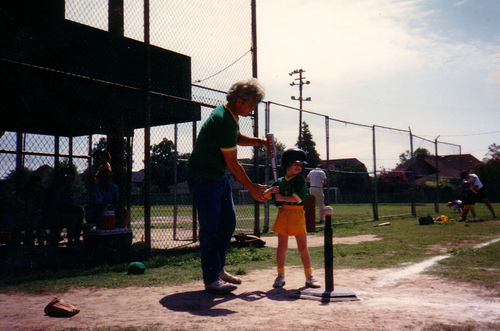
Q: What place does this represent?
A: It represents the field.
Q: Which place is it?
A: It is a field.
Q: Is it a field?
A: Yes, it is a field.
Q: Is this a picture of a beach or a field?
A: It is showing a field.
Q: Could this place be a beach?
A: No, it is a field.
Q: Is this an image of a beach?
A: No, the picture is showing a field.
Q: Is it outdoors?
A: Yes, it is outdoors.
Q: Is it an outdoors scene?
A: Yes, it is outdoors.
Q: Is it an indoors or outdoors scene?
A: It is outdoors.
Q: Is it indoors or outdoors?
A: It is outdoors.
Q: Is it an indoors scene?
A: No, it is outdoors.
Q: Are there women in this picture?
A: No, there are no women.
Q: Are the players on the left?
A: Yes, the players are on the left of the image.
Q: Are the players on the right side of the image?
A: No, the players are on the left of the image.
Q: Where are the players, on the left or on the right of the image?
A: The players are on the left of the image.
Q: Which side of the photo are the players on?
A: The players are on the left of the image.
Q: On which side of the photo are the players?
A: The players are on the left of the image.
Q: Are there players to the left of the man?
A: Yes, there are players to the left of the man.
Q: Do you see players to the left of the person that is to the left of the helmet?
A: Yes, there are players to the left of the man.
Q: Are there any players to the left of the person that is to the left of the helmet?
A: Yes, there are players to the left of the man.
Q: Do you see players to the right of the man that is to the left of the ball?
A: No, the players are to the left of the man.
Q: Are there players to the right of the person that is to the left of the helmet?
A: No, the players are to the left of the man.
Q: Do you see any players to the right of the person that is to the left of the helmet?
A: No, the players are to the left of the man.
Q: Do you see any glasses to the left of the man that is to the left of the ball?
A: No, there are players to the left of the man.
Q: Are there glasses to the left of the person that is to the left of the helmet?
A: No, there are players to the left of the man.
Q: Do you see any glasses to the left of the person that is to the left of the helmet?
A: No, there are players to the left of the man.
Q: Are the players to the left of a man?
A: Yes, the players are to the left of a man.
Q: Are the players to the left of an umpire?
A: No, the players are to the left of a man.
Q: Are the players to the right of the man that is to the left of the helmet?
A: No, the players are to the left of the man.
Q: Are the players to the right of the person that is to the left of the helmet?
A: No, the players are to the left of the man.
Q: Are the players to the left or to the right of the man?
A: The players are to the left of the man.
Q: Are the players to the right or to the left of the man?
A: The players are to the left of the man.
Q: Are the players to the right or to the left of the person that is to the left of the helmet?
A: The players are to the left of the man.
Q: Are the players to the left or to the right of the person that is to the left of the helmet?
A: The players are to the left of the man.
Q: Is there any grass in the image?
A: Yes, there is grass.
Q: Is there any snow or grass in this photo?
A: Yes, there is grass.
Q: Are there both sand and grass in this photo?
A: No, there is grass but no sand.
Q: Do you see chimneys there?
A: No, there are no chimneys.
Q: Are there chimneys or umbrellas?
A: No, there are no chimneys or umbrellas.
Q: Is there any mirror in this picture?
A: No, there are no mirrors.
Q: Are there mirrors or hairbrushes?
A: No, there are no mirrors or hairbrushes.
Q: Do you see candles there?
A: No, there are no candles.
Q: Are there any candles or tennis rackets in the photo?
A: No, there are no candles or tennis rackets.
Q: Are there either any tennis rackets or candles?
A: No, there are no candles or tennis rackets.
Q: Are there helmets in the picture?
A: Yes, there is a helmet.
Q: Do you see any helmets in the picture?
A: Yes, there is a helmet.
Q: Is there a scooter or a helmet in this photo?
A: Yes, there is a helmet.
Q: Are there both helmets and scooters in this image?
A: No, there is a helmet but no scooters.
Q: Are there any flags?
A: No, there are no flags.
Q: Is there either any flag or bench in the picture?
A: No, there are no flags or benches.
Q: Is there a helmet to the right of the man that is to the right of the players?
A: Yes, there is a helmet to the right of the man.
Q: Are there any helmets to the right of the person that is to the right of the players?
A: Yes, there is a helmet to the right of the man.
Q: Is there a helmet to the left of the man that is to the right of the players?
A: No, the helmet is to the right of the man.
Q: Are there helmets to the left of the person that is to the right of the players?
A: No, the helmet is to the right of the man.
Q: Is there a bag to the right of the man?
A: No, there is a helmet to the right of the man.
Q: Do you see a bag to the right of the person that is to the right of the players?
A: No, there is a helmet to the right of the man.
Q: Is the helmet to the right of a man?
A: Yes, the helmet is to the right of a man.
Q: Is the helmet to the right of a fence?
A: No, the helmet is to the right of a man.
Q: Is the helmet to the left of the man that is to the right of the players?
A: No, the helmet is to the right of the man.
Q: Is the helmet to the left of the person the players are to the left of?
A: No, the helmet is to the right of the man.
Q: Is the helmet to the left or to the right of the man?
A: The helmet is to the right of the man.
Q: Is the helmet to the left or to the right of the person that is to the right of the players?
A: The helmet is to the right of the man.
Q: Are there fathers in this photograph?
A: No, there are no fathers.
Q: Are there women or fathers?
A: No, there are no fathers or women.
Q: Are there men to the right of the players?
A: Yes, there is a man to the right of the players.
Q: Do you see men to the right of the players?
A: Yes, there is a man to the right of the players.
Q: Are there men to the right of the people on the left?
A: Yes, there is a man to the right of the players.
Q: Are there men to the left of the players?
A: No, the man is to the right of the players.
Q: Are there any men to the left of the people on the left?
A: No, the man is to the right of the players.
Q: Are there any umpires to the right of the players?
A: No, there is a man to the right of the players.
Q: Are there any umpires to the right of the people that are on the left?
A: No, there is a man to the right of the players.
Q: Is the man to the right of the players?
A: Yes, the man is to the right of the players.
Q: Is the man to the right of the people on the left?
A: Yes, the man is to the right of the players.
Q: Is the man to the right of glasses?
A: No, the man is to the right of the players.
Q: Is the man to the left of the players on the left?
A: No, the man is to the right of the players.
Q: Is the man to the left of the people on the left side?
A: No, the man is to the right of the players.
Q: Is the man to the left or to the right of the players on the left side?
A: The man is to the right of the players.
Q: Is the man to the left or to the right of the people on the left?
A: The man is to the right of the players.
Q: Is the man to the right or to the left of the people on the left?
A: The man is to the right of the players.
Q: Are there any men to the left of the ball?
A: Yes, there is a man to the left of the ball.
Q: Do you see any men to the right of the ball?
A: No, the man is to the left of the ball.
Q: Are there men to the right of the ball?
A: No, the man is to the left of the ball.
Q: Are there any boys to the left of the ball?
A: No, there is a man to the left of the ball.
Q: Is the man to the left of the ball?
A: Yes, the man is to the left of the ball.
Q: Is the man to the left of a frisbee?
A: No, the man is to the left of the ball.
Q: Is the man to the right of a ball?
A: No, the man is to the left of a ball.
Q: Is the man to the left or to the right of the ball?
A: The man is to the left of the ball.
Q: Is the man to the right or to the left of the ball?
A: The man is to the left of the ball.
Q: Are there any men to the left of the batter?
A: Yes, there is a man to the left of the batter.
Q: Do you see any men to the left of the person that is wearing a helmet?
A: Yes, there is a man to the left of the batter.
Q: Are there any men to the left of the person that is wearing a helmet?
A: Yes, there is a man to the left of the batter.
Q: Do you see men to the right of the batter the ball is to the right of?
A: No, the man is to the left of the batter.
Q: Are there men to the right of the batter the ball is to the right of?
A: No, the man is to the left of the batter.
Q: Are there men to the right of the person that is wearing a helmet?
A: No, the man is to the left of the batter.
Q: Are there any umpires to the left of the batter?
A: No, there is a man to the left of the batter.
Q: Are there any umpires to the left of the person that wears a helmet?
A: No, there is a man to the left of the batter.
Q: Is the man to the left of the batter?
A: Yes, the man is to the left of the batter.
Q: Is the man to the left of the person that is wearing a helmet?
A: Yes, the man is to the left of the batter.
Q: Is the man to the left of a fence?
A: No, the man is to the left of the batter.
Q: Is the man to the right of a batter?
A: No, the man is to the left of a batter.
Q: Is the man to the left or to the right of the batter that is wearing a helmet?
A: The man is to the left of the batter.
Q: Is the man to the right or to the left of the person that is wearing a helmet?
A: The man is to the left of the batter.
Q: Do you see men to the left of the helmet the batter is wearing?
A: Yes, there is a man to the left of the helmet.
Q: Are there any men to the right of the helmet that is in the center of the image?
A: No, the man is to the left of the helmet.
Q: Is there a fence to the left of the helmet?
A: No, there is a man to the left of the helmet.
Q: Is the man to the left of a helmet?
A: Yes, the man is to the left of a helmet.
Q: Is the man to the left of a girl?
A: No, the man is to the left of a helmet.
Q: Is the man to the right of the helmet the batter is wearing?
A: No, the man is to the left of the helmet.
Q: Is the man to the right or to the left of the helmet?
A: The man is to the left of the helmet.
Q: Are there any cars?
A: No, there are no cars.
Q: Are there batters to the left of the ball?
A: Yes, there is a batter to the left of the ball.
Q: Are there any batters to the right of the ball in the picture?
A: No, the batter is to the left of the ball.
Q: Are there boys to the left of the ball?
A: No, there is a batter to the left of the ball.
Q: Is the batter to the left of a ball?
A: Yes, the batter is to the left of a ball.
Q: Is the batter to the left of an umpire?
A: No, the batter is to the left of a ball.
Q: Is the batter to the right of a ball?
A: No, the batter is to the left of a ball.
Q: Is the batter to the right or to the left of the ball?
A: The batter is to the left of the ball.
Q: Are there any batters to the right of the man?
A: Yes, there is a batter to the right of the man.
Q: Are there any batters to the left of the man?
A: No, the batter is to the right of the man.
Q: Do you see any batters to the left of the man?
A: No, the batter is to the right of the man.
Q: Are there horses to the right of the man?
A: No, there is a batter to the right of the man.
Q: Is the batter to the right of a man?
A: Yes, the batter is to the right of a man.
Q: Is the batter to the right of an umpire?
A: No, the batter is to the right of a man.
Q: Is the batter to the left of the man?
A: No, the batter is to the right of the man.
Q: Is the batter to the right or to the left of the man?
A: The batter is to the right of the man.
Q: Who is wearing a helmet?
A: The batter is wearing a helmet.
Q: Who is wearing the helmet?
A: The batter is wearing a helmet.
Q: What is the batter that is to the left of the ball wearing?
A: The batter is wearing a helmet.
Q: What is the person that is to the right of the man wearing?
A: The batter is wearing a helmet.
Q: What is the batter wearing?
A: The batter is wearing a helmet.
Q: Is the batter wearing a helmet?
A: Yes, the batter is wearing a helmet.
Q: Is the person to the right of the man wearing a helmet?
A: Yes, the batter is wearing a helmet.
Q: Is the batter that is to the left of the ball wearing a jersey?
A: No, the batter is wearing a helmet.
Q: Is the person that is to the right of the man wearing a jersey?
A: No, the batter is wearing a helmet.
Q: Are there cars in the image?
A: No, there are no cars.